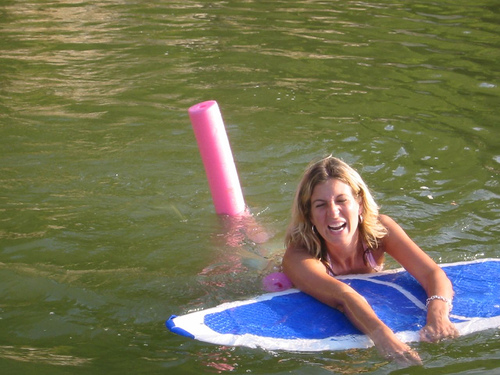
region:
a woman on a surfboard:
[155, 152, 496, 365]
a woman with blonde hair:
[277, 156, 392, 253]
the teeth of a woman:
[321, 216, 346, 231]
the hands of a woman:
[360, 300, 460, 365]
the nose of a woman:
[325, 202, 342, 213]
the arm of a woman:
[385, 212, 480, 338]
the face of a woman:
[307, 185, 362, 232]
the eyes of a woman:
[311, 194, 345, 212]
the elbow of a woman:
[327, 295, 354, 318]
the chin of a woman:
[335, 237, 347, 247]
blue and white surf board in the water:
[169, 253, 494, 372]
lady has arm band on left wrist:
[406, 277, 473, 330]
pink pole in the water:
[179, 91, 244, 243]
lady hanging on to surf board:
[253, 220, 448, 366]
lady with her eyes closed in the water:
[287, 156, 389, 248]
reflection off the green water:
[24, 17, 224, 131]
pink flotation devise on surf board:
[249, 270, 287, 299]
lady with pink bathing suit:
[350, 235, 385, 275]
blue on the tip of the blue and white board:
[164, 308, 200, 346]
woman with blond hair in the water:
[291, 157, 380, 249]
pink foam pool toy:
[174, 88, 273, 255]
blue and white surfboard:
[164, 246, 497, 360]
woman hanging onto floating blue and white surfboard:
[156, 130, 496, 369]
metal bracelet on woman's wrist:
[420, 289, 452, 312]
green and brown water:
[1, 1, 488, 373]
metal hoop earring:
[306, 221, 323, 238]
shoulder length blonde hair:
[280, 143, 387, 260]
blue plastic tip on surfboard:
[158, 307, 196, 346]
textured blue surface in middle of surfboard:
[206, 258, 496, 340]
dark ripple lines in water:
[413, 53, 499, 98]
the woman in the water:
[270, 145, 465, 373]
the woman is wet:
[267, 153, 497, 344]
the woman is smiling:
[275, 146, 385, 246]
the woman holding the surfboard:
[256, 140, 473, 361]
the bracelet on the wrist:
[425, 286, 452, 316]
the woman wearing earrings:
[280, 161, 370, 246]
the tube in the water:
[162, 90, 262, 225]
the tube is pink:
[175, 95, 255, 212]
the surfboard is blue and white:
[155, 255, 495, 355]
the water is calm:
[30, 27, 173, 95]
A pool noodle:
[183, 100, 253, 222]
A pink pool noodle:
[190, 100, 250, 214]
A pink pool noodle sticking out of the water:
[186, 100, 246, 217]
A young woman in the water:
[275, 160, 472, 362]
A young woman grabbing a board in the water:
[162, 159, 497, 365]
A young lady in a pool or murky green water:
[2, 0, 499, 374]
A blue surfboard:
[170, 257, 499, 348]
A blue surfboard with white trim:
[170, 257, 499, 352]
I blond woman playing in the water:
[266, 157, 455, 362]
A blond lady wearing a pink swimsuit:
[265, 157, 465, 365]